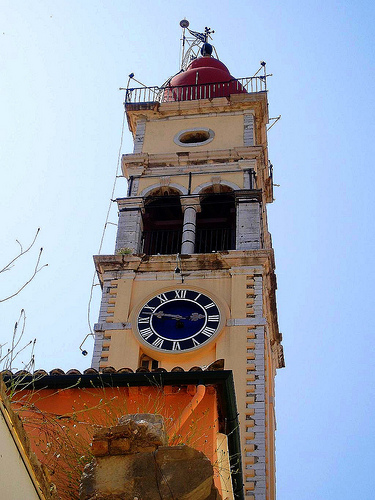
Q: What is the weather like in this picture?
A: It is cloudless.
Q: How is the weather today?
A: It is cloudless.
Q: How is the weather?
A: It is cloudless.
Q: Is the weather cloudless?
A: Yes, it is cloudless.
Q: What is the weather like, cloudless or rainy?
A: It is cloudless.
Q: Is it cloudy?
A: No, it is cloudless.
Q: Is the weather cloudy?
A: No, it is cloudless.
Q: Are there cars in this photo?
A: No, there are no cars.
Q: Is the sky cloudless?
A: Yes, the sky is cloudless.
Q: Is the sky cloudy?
A: No, the sky is cloudless.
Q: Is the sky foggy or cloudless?
A: The sky is cloudless.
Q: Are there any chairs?
A: No, there are no chairs.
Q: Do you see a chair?
A: No, there are no chairs.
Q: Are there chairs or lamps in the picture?
A: No, there are no chairs or lamps.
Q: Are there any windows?
A: Yes, there is a window.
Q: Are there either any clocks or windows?
A: Yes, there is a window.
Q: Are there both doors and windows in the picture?
A: No, there is a window but no doors.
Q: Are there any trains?
A: No, there are no trains.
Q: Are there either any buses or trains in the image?
A: No, there are no trains or buses.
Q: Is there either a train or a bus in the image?
A: No, there are no trains or buses.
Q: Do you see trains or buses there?
A: No, there are no trains or buses.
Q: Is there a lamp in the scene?
A: No, there are no lamps.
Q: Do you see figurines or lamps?
A: No, there are no lamps or figurines.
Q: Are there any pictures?
A: No, there are no pictures.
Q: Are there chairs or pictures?
A: No, there are no pictures or chairs.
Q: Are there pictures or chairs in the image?
A: No, there are no pictures or chairs.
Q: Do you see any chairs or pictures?
A: No, there are no pictures or chairs.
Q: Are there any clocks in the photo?
A: Yes, there is a clock.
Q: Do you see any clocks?
A: Yes, there is a clock.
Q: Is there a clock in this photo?
A: Yes, there is a clock.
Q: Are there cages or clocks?
A: Yes, there is a clock.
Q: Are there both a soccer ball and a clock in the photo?
A: No, there is a clock but no soccer balls.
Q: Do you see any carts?
A: No, there are no carts.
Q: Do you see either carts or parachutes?
A: No, there are no carts or parachutes.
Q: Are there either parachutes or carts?
A: No, there are no carts or parachutes.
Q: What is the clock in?
A: The clock is in the tower.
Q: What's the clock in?
A: The clock is in the tower.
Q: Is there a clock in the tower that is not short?
A: Yes, there is a clock in the tower.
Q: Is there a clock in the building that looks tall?
A: Yes, there is a clock in the tower.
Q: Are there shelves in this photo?
A: No, there are no shelves.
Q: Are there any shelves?
A: No, there are no shelves.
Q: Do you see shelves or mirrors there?
A: No, there are no shelves or mirrors.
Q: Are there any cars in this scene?
A: No, there are no cars.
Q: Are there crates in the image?
A: No, there are no crates.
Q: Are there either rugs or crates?
A: No, there are no crates or rugs.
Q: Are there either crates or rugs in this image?
A: No, there are no crates or rugs.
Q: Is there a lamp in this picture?
A: No, there are no lamps.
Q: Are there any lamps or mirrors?
A: No, there are no lamps or mirrors.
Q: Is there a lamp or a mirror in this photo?
A: No, there are no lamps or mirrors.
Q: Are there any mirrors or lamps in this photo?
A: No, there are no lamps or mirrors.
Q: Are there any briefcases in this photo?
A: No, there are no briefcases.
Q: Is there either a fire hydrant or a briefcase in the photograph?
A: No, there are no briefcases or fire hydrants.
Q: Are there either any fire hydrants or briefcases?
A: No, there are no briefcases or fire hydrants.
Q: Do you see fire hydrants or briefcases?
A: No, there are no briefcases or fire hydrants.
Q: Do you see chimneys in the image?
A: No, there are no chimneys.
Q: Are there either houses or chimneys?
A: No, there are no chimneys or houses.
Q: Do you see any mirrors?
A: No, there are no mirrors.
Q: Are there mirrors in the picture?
A: No, there are no mirrors.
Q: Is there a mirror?
A: No, there are no mirrors.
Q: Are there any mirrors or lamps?
A: No, there are no mirrors or lamps.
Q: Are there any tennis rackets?
A: No, there are no tennis rackets.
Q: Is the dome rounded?
A: Yes, the dome is rounded.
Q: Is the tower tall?
A: Yes, the tower is tall.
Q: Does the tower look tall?
A: Yes, the tower is tall.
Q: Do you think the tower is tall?
A: Yes, the tower is tall.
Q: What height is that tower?
A: The tower is tall.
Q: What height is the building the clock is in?
A: The tower is tall.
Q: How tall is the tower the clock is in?
A: The tower is tall.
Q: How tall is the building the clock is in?
A: The tower is tall.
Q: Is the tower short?
A: No, the tower is tall.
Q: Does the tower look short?
A: No, the tower is tall.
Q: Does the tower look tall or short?
A: The tower is tall.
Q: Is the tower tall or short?
A: The tower is tall.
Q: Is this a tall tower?
A: Yes, this is a tall tower.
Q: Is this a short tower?
A: No, this is a tall tower.